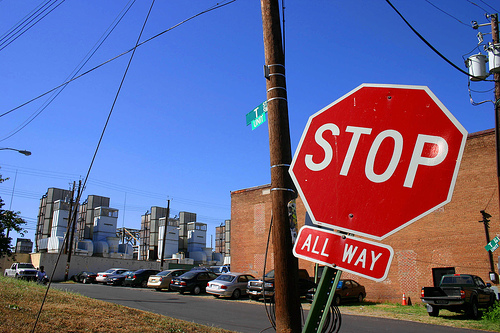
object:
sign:
[288, 84, 469, 241]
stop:
[304, 123, 449, 188]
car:
[205, 272, 255, 298]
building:
[229, 126, 498, 306]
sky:
[0, 1, 499, 253]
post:
[262, 1, 302, 333]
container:
[157, 217, 177, 224]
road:
[46, 280, 488, 332]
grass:
[1, 281, 240, 331]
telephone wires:
[0, 1, 236, 116]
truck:
[4, 262, 38, 280]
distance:
[0, 1, 499, 218]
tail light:
[421, 289, 424, 297]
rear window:
[216, 275, 235, 282]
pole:
[300, 265, 341, 332]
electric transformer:
[464, 53, 488, 82]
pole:
[490, 13, 500, 196]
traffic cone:
[402, 292, 407, 306]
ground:
[3, 277, 499, 331]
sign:
[245, 101, 266, 132]